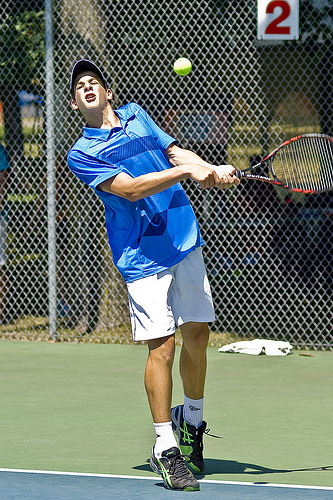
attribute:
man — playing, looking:
[50, 59, 227, 354]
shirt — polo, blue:
[138, 162, 152, 172]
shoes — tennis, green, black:
[176, 413, 198, 475]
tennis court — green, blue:
[57, 376, 117, 416]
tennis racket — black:
[239, 143, 316, 198]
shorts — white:
[139, 288, 210, 333]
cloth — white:
[229, 337, 282, 353]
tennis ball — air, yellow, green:
[162, 57, 200, 78]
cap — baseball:
[69, 59, 90, 73]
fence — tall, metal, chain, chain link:
[152, 12, 203, 28]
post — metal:
[44, 5, 53, 31]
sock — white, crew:
[148, 426, 177, 451]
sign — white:
[253, 0, 301, 49]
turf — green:
[66, 332, 92, 353]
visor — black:
[89, 64, 105, 74]